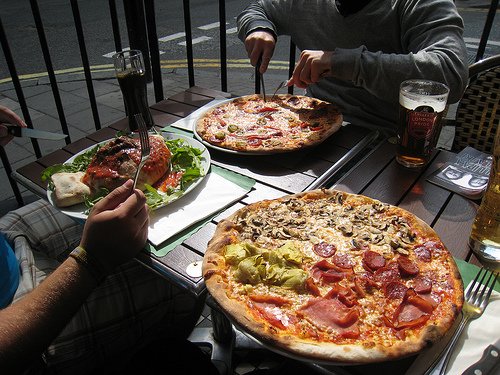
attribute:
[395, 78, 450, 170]
glass — tall, promotional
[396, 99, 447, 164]
beer — dark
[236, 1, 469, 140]
person — cutting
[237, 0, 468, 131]
jacket — grey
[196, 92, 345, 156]
pizza — medium-sized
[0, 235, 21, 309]
shirt — blue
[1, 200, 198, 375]
shorts — plaid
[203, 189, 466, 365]
pizza — whole, uncut, large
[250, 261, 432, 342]
ham — thinly sliced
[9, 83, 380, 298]
table — square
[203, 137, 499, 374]
table — square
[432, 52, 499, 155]
chair — partial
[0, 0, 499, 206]
fence — black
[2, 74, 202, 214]
sidewalk — brick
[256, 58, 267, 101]
knife — cutting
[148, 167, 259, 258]
placemat — green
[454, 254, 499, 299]
placemat — green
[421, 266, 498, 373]
fork — metal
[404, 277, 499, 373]
napkin — white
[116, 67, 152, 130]
beer — dark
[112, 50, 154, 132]
glass — tall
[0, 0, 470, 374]
people — eating